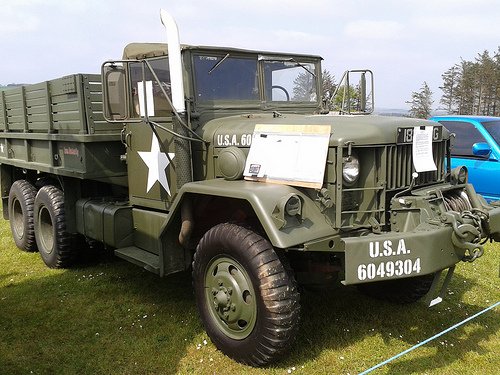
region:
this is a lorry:
[0, 23, 461, 295]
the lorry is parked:
[4, 53, 442, 320]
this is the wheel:
[258, 249, 296, 341]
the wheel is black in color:
[232, 261, 302, 356]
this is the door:
[130, 113, 165, 192]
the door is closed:
[121, 128, 168, 189]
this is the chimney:
[156, 3, 184, 35]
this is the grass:
[64, 290, 159, 370]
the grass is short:
[56, 296, 163, 371]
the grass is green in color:
[68, 285, 158, 363]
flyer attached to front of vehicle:
[410, 124, 442, 173]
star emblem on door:
[138, 124, 178, 196]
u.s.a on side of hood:
[215, 133, 241, 146]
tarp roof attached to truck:
[119, 40, 169, 65]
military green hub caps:
[200, 252, 256, 338]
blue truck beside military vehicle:
[425, 110, 496, 196]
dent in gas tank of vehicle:
[80, 201, 100, 238]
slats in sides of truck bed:
[0, 70, 125, 136]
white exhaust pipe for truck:
[160, 15, 196, 120]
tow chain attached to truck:
[439, 186, 492, 263]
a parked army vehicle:
[0, 49, 495, 364]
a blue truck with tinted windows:
[425, 114, 498, 199]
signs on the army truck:
[243, 119, 441, 207]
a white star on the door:
[124, 122, 184, 207]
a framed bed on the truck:
[0, 61, 120, 181]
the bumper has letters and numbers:
[347, 238, 429, 280]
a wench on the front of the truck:
[407, 189, 499, 269]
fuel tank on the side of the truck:
[71, 193, 139, 258]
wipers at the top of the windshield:
[185, 45, 330, 77]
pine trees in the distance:
[417, 47, 497, 117]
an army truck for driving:
[32, 16, 499, 311]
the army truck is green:
[99, 42, 478, 299]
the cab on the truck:
[3, 69, 128, 191]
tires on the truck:
[2, 176, 322, 354]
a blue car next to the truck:
[422, 99, 499, 194]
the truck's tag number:
[346, 214, 467, 293]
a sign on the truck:
[224, 97, 346, 206]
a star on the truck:
[106, 124, 208, 211]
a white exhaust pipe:
[144, 2, 198, 123]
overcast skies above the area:
[229, 7, 474, 69]